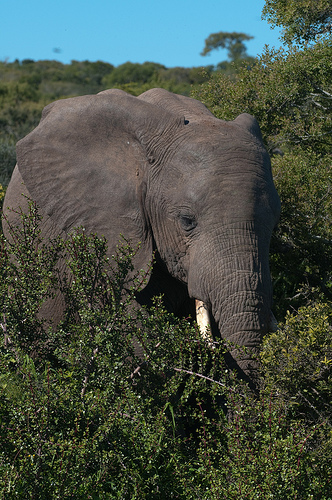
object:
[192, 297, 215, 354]
tusk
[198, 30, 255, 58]
tree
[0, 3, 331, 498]
leaves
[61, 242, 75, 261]
stems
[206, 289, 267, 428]
tusk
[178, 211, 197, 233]
eye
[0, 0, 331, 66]
sky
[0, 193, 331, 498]
visible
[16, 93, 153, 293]
ear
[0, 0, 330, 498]
brush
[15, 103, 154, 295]
large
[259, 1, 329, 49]
tree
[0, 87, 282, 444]
elephant